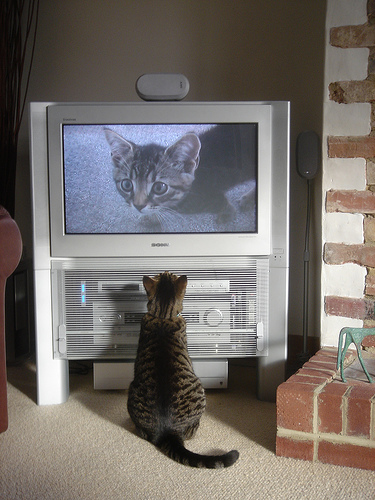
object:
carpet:
[256, 463, 361, 498]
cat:
[127, 271, 240, 470]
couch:
[65, 266, 320, 457]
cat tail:
[154, 431, 239, 470]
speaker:
[137, 73, 189, 100]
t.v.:
[47, 103, 273, 256]